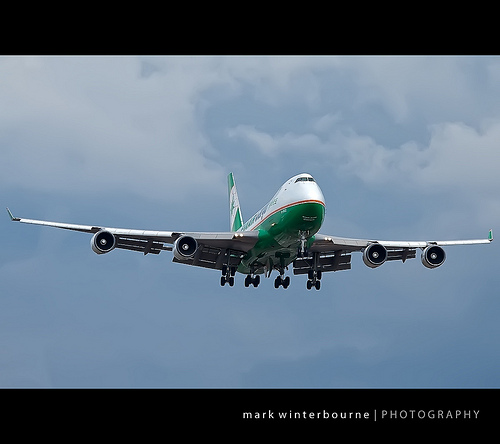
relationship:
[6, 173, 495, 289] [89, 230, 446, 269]
jet has engines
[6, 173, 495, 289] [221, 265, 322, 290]
jet has wheels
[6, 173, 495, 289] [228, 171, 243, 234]
jet has tail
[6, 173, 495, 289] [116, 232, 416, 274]
plane has flaps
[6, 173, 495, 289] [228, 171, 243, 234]
jet has vertical stabilizer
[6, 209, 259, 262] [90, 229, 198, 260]
wing has engines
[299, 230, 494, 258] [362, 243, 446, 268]
wing has engines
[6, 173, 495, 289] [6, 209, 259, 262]
jet has wing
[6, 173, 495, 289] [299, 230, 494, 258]
jet has wing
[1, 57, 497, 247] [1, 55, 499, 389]
clouds in sky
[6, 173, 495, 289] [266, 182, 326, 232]
jet has nose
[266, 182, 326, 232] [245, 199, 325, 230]
nose has stripe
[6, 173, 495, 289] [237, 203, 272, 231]
jet has name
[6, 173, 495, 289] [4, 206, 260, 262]
plane has wing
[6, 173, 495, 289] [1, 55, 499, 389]
jet in skies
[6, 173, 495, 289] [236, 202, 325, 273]
jet has belly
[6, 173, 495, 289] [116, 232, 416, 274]
jet has flaps